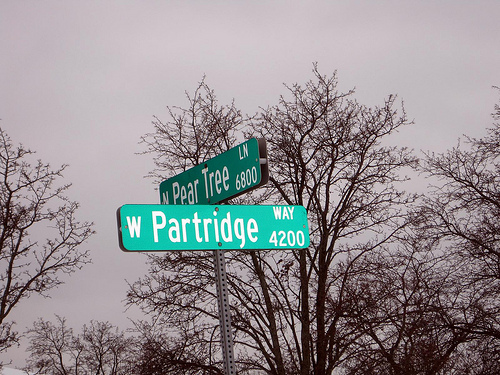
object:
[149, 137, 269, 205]
sign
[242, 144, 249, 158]
letters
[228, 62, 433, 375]
bare trees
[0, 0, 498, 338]
sky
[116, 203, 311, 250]
sign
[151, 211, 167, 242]
letter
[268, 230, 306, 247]
numbers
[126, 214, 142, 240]
letter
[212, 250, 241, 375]
pole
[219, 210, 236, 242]
letter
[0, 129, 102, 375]
tree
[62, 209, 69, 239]
branches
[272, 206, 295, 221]
word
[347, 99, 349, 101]
leaves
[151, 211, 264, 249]
writing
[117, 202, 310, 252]
background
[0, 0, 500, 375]
field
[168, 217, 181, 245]
letter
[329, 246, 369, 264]
branches